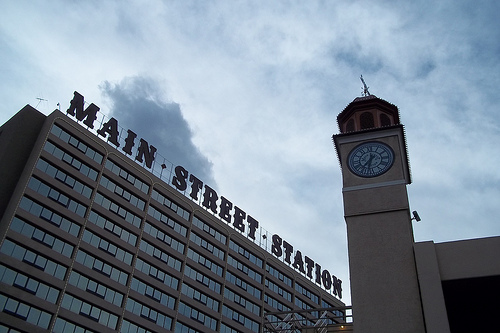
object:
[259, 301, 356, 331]
handrail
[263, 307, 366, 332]
balcony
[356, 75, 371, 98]
statue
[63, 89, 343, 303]
sign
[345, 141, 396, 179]
clock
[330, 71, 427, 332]
tower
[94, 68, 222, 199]
cloud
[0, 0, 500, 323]
sky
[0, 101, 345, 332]
building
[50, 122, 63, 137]
window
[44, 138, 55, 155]
window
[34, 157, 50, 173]
window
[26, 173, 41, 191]
window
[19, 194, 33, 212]
window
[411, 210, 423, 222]
security camera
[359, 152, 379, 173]
6:35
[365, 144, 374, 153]
roman numerals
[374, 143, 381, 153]
roman numerals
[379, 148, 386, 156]
roman numerals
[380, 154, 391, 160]
roman numerals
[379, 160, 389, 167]
roman numerals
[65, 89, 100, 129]
letter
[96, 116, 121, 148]
letter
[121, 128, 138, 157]
letter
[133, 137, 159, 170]
letter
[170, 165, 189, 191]
letter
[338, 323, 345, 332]
light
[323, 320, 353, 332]
wall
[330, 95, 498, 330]
building